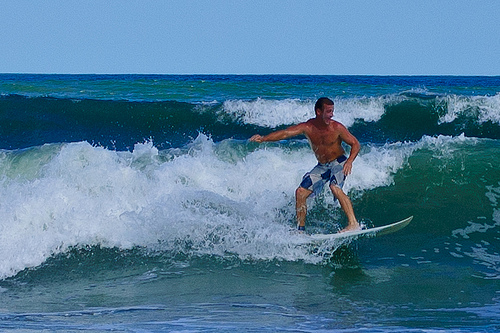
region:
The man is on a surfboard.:
[243, 90, 429, 252]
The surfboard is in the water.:
[238, 91, 420, 254]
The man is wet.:
[242, 90, 422, 253]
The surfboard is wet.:
[236, 93, 419, 254]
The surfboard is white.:
[244, 91, 426, 256]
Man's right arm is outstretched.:
[236, 94, 425, 250]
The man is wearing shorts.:
[244, 85, 421, 254]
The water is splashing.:
[1, 70, 498, 328]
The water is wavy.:
[2, 70, 499, 331]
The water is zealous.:
[1, 69, 498, 331]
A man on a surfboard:
[245, 96, 419, 240]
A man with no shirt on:
[306, 118, 348, 164]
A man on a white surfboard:
[302, 211, 418, 241]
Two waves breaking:
[1, 88, 499, 285]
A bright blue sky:
[0, 1, 499, 77]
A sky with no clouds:
[1, 0, 499, 79]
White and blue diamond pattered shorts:
[298, 151, 351, 193]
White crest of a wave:
[217, 91, 393, 127]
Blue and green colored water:
[0, 75, 499, 331]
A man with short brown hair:
[313, 96, 335, 113]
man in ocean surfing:
[251, 77, 411, 264]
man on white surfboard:
[248, 69, 423, 270]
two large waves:
[410, 66, 488, 202]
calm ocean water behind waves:
[138, 67, 250, 89]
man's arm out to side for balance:
[228, 115, 317, 186]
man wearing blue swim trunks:
[282, 138, 365, 222]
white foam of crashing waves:
[35, 129, 163, 274]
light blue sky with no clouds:
[213, 28, 347, 49]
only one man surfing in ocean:
[200, 40, 495, 271]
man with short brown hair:
[314, 79, 351, 138]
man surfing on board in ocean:
[243, 96, 389, 246]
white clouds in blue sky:
[23, 9, 78, 53]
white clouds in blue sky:
[35, 125, 104, 178]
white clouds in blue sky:
[137, 136, 200, 212]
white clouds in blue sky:
[207, 180, 264, 253]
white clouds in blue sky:
[132, 21, 192, 59]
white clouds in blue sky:
[267, 20, 333, 54]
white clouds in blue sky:
[408, 118, 465, 203]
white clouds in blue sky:
[370, 15, 444, 62]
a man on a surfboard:
[228, 75, 419, 265]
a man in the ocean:
[233, 86, 423, 253]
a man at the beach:
[246, 86, 430, 256]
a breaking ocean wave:
[0, 134, 242, 297]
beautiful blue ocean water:
[1, 72, 245, 327]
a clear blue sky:
[1, 0, 496, 70]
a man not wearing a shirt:
[250, 92, 368, 177]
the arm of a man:
[240, 115, 307, 151]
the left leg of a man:
[328, 178, 365, 232]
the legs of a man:
[292, 163, 359, 231]